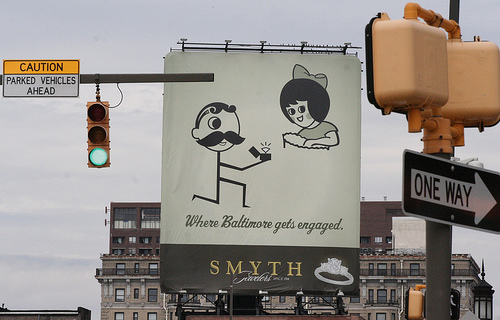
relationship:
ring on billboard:
[257, 142, 274, 154] [158, 39, 362, 287]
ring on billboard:
[313, 256, 354, 287] [158, 39, 362, 287]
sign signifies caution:
[2, 57, 83, 98] [2, 59, 81, 75]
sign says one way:
[400, 147, 498, 235] [412, 167, 474, 209]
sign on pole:
[400, 147, 498, 235] [421, 153, 455, 318]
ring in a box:
[257, 142, 274, 154] [248, 145, 272, 161]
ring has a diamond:
[257, 142, 274, 154] [260, 144, 271, 153]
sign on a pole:
[400, 147, 498, 235] [421, 153, 455, 318]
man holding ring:
[189, 101, 274, 213] [257, 142, 274, 154]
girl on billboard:
[279, 61, 341, 155] [158, 39, 362, 287]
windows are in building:
[112, 204, 456, 319] [94, 201, 482, 318]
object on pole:
[363, 3, 498, 155] [421, 153, 455, 318]